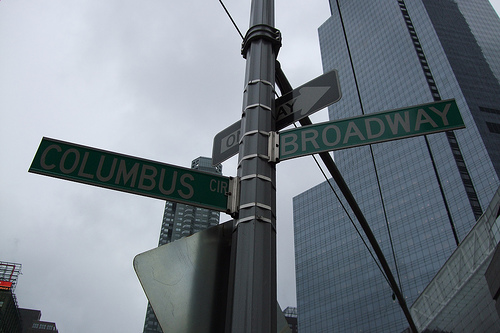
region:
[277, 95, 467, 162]
a green street sign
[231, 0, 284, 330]
a gray metal pole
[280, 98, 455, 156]
white writing on the sign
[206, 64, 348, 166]
a black and white sign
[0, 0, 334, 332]
a gray cloudy sky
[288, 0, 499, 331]
a tall building covered in glass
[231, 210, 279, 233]
a metal ring on the pole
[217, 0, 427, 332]
a black wire in the air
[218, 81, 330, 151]
a white arrow on the sign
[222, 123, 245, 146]
black writing on the sign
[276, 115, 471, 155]
green street sign on pole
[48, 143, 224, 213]
green street sign on pole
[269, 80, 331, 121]
arrow on street sign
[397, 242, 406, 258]
window on front of skyscraper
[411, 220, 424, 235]
window on front of skyscraper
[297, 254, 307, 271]
window on front of skyscraper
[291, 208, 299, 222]
window on front of skyscraper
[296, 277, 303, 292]
window on front of skyscraper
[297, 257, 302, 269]
window on front of skyscraper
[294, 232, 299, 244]
window on front of skyscraper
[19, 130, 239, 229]
A sign post sign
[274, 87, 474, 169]
A sign post sign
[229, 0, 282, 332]
A pole post in the picture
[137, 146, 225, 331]
A very tall building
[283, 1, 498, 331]
A very tall building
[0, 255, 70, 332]
Very tall buildings in the picture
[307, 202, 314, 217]
Window of a building in the picture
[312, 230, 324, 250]
Window of a building in the picture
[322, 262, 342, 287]
Window of a building in the picture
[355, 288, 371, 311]
Window of a building in the picture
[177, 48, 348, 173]
Black and white sign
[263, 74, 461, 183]
The sign says Broadway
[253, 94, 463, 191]
Green and white sign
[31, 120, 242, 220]
The sign says Columbus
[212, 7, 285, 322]
The pole is black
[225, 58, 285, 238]
Silver rings on the pole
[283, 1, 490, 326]
Tall, large sky scraper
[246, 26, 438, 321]
Black wire attached to pole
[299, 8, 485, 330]
The sky scraper has many windows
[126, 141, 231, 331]
The building has many floors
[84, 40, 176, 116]
this is the sky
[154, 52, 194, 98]
the sky is blue in color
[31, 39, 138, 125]
the sky has some clouds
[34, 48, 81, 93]
the clouds are white in color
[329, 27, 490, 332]
this is a building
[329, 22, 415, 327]
the building is tall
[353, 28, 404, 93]
the windows are many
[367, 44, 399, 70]
the windows are made of glass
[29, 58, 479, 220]
these are street signs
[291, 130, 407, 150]
the writings are in bold